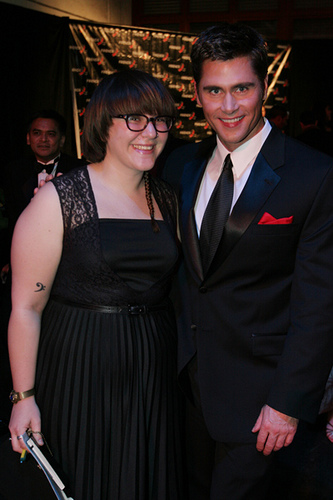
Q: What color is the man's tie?
A: Black.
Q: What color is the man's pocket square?
A: Red.